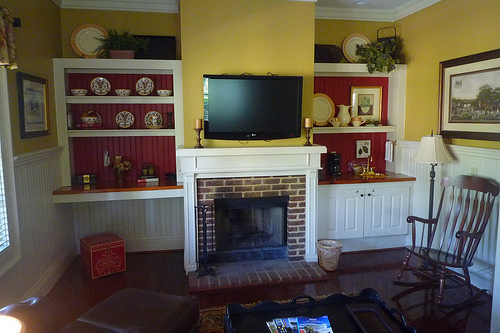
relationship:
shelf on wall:
[65, 95, 174, 104] [177, 0, 317, 190]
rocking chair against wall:
[389, 173, 498, 311] [386, 172, 496, 309]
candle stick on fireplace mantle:
[187, 127, 208, 147] [174, 142, 332, 177]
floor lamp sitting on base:
[410, 129, 455, 275] [426, 159, 436, 252]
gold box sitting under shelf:
[62, 220, 163, 281] [53, 180, 183, 205]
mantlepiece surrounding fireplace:
[172, 140, 333, 294] [192, 170, 308, 270]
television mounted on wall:
[195, 71, 304, 146] [181, 0, 313, 145]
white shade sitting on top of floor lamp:
[410, 134, 452, 163] [412, 130, 454, 215]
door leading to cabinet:
[317, 187, 365, 240] [317, 184, 412, 241]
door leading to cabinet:
[363, 185, 411, 238] [317, 184, 412, 241]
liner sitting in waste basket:
[312, 235, 343, 255] [317, 235, 345, 273]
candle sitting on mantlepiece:
[300, 113, 315, 148] [173, 143, 326, 177]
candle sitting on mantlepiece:
[191, 117, 203, 149] [173, 143, 326, 177]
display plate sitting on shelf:
[88, 76, 112, 95] [63, 91, 174, 105]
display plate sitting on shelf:
[132, 75, 154, 95] [63, 91, 174, 105]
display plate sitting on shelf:
[81, 109, 101, 127] [65, 125, 174, 137]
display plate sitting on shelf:
[111, 108, 134, 128] [65, 125, 174, 137]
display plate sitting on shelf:
[140, 110, 164, 129] [65, 125, 174, 137]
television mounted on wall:
[203, 74, 304, 140] [181, 0, 313, 145]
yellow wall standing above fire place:
[186, 7, 306, 68] [191, 163, 311, 258]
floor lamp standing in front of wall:
[410, 129, 455, 275] [309, 33, 498, 252]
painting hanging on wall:
[435, 45, 485, 142] [386, 10, 493, 187]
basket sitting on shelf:
[355, 26, 425, 73] [311, 47, 495, 182]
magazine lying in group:
[265, 319, 275, 330] [263, 313, 334, 331]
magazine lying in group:
[273, 316, 285, 330] [263, 313, 334, 331]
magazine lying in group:
[280, 316, 291, 331] [263, 313, 334, 331]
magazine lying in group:
[285, 314, 299, 331] [263, 313, 334, 331]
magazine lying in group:
[291, 312, 331, 331] [263, 313, 334, 331]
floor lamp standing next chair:
[410, 129, 455, 275] [404, 176, 485, 298]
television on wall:
[203, 74, 304, 140] [205, 17, 293, 62]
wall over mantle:
[205, 17, 293, 62] [175, 141, 329, 152]